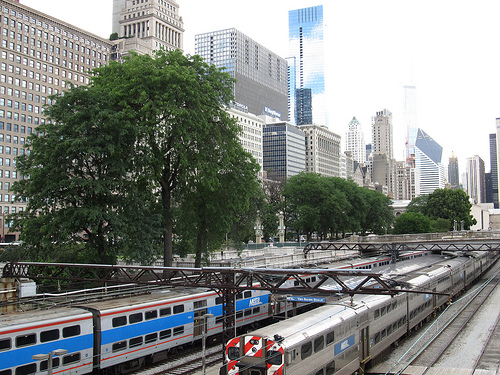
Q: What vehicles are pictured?
A: Trains.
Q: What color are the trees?
A: Green.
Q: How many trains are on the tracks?
A: 2.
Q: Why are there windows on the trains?
A: So passengers can see.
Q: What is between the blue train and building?
A: Trees.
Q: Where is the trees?
A: Beside the train.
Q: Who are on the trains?
A: Passengers.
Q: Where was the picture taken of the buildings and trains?
A: Downtown city.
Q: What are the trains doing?
A: Moving on tracks.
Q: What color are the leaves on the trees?
A: Green.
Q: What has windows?
A: Building.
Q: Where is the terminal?
A: In the city.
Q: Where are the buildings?
A: In the city.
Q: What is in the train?
A: Passengers.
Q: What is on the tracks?
A: Trains.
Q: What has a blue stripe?
A: Train.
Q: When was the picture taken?
A: Daytime.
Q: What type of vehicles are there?
A: Trains.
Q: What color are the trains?
A: Silver, blue and red.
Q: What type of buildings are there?
A: Skyscrapers.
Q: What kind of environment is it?
A: Urban.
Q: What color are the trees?
A: Green.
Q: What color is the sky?
A: White.